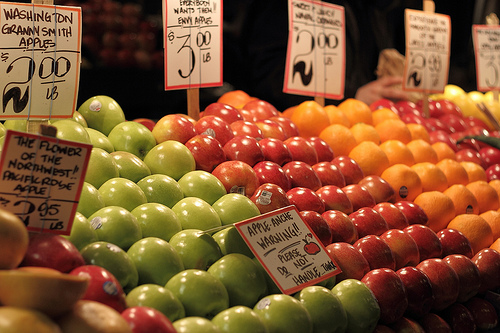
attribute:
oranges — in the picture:
[266, 86, 497, 268]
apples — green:
[143, 138, 197, 185]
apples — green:
[174, 167, 226, 206]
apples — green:
[211, 191, 267, 231]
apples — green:
[106, 119, 156, 163]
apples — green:
[77, 93, 128, 139]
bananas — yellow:
[430, 81, 498, 135]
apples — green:
[83, 118, 341, 298]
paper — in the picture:
[2, 1, 86, 121]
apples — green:
[18, 119, 359, 329]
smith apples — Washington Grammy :
[101, 165, 181, 240]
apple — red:
[184, 133, 222, 174]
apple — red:
[284, 135, 321, 162]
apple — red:
[363, 173, 393, 203]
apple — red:
[289, 183, 324, 214]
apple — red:
[382, 232, 417, 264]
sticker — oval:
[397, 182, 409, 198]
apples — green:
[25, 99, 368, 320]